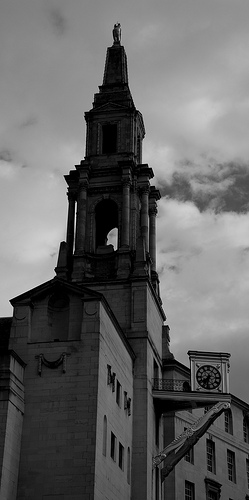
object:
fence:
[152, 371, 190, 392]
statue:
[111, 21, 122, 46]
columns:
[76, 176, 89, 254]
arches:
[90, 189, 125, 252]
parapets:
[85, 46, 144, 163]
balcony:
[150, 363, 190, 392]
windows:
[205, 434, 217, 474]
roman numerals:
[198, 379, 202, 384]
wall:
[29, 337, 94, 491]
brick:
[77, 404, 94, 420]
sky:
[144, 3, 248, 117]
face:
[196, 361, 222, 391]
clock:
[196, 360, 222, 392]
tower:
[62, 17, 161, 264]